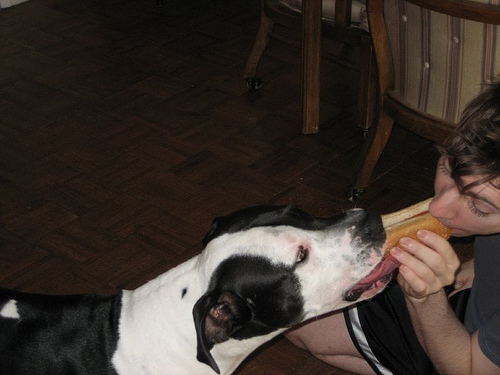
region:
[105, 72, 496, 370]
A dog and a man are sharing a hot dog.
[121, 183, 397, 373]
The dog is biting one end of the hot dog.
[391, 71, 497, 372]
The man is biting the other end of the hot dog.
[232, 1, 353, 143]
A chair next to a table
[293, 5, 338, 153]
The leg of the table.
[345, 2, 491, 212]
The second chair next to the table.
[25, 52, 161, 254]
The floor has wood boards on it.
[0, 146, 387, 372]
The dog is black and white.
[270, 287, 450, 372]
The man is wearing shorts.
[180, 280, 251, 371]
The dog has a black ear.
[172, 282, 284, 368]
the dog is black and white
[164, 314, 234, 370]
the dog is black and white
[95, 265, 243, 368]
the dog is black and white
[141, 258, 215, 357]
the dog is black and white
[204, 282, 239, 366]
the dog is black and white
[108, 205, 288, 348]
the dog is black and white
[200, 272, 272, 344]
the dog is black and white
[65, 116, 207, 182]
part of the floor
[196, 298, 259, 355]
ear on the dog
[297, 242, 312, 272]
eye on the dog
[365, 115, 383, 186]
leg on the chair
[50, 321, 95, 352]
black fur on dog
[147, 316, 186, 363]
white fur on dog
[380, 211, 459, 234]
part of hot dog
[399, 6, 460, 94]
back part of chair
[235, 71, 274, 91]
coaster on the chair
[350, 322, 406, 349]
part of man's shorts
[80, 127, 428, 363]
a black and white dog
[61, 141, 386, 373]
a black and white dog inside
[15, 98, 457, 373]
a dog that is inside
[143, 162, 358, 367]
a dog with black ears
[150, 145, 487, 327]
a dog eating a hotdog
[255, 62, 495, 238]
a boy eating a hotdog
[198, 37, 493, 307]
a dog and boy sharing a hotdog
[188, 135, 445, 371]
a dog biting into a hotdog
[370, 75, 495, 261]
a boy biting into a hotdog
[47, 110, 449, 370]
a dog with a white neck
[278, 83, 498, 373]
The boy is holding a hotdog.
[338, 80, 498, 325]
Boy's mouth is over the hotdog.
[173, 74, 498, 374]
The dog is biting other end of hotdog.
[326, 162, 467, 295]
The hotdog in on a bun.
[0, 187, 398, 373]
The dog is short-haired.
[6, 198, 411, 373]
Dog's tongue is sticking out.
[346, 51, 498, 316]
The boy has hair.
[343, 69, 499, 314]
Boy's hair is tousled.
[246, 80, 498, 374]
The boy is wearing shorts.